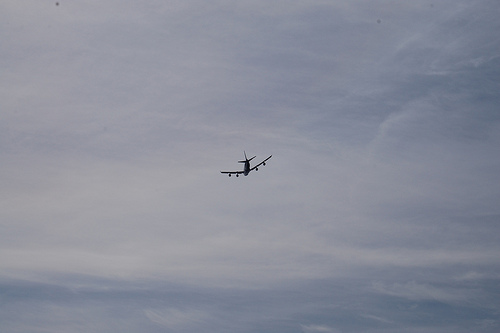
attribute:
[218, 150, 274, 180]
plane — tilted, flying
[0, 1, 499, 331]
sky — blue, clear, cloudy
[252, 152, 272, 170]
wing — horizontal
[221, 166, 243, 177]
wing — horizontal